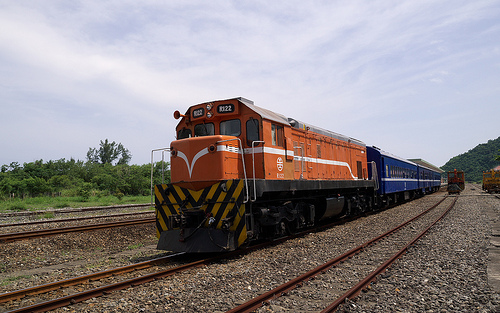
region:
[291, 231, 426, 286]
the train tracks are rusty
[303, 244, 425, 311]
the train tracks are rusty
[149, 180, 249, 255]
yellow and black lines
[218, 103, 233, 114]
black and white number on the train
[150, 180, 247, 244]
black and yellow stripes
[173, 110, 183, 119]
a horn on the train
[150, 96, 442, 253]
a train on the tracks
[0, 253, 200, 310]
rust color train tracks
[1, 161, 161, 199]
bushes past the train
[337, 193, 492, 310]
gravel by the tracks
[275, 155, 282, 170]
white logo on the train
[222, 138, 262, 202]
white hand railing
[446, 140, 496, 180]
small hillside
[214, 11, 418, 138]
The sky is blue and white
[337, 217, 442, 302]
Gravel is between the tracks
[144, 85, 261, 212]
The front of the train has windows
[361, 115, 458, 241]
The train cars are blue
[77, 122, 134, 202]
The tree is tall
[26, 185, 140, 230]
The grass is green and tall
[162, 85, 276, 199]
The front of the train is orange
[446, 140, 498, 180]
Mountains are in the back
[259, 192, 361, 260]
The train is on the tracks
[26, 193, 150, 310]
The tracks are metal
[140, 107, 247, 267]
front of the train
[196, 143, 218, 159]
a white line in the train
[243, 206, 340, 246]
wheel of the train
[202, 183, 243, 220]
a group of yellow lines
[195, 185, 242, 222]
a group of black lines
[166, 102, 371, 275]
engine of the train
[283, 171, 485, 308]
a long rail way track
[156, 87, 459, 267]
a train in the track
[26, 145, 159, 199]
a part of trees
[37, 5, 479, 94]
a white sky in the top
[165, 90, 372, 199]
the train is orange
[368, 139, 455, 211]
train's car is blue